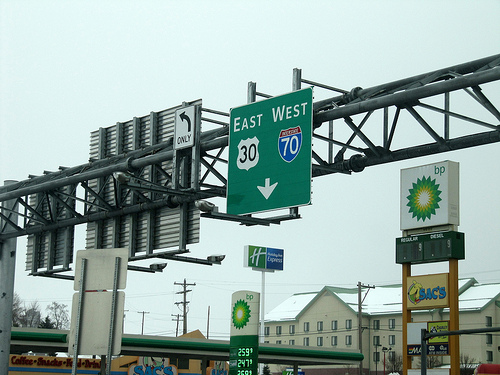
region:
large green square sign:
[225, 88, 314, 217]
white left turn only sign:
[175, 105, 194, 150]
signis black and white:
[172, 105, 195, 151]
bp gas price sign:
[226, 289, 258, 374]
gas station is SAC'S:
[9, 328, 362, 374]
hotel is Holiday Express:
[259, 276, 499, 373]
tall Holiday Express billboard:
[243, 245, 285, 342]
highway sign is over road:
[225, 85, 312, 216]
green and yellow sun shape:
[231, 298, 249, 328]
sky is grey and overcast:
[1, 0, 498, 339]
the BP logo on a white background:
[228, 290, 261, 336]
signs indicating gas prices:
[230, 335, 257, 373]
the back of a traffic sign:
[68, 248, 128, 357]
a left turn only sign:
[172, 103, 197, 148]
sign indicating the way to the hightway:
[224, 85, 312, 218]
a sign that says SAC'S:
[404, 271, 451, 311]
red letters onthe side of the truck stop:
[8, 353, 103, 368]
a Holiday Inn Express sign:
[243, 243, 285, 273]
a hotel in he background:
[260, 278, 498, 373]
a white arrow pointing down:
[255, 173, 279, 203]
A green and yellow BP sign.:
[395, 160, 456, 229]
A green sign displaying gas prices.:
[222, 346, 257, 373]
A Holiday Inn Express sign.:
[246, 247, 286, 268]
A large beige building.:
[262, 278, 497, 370]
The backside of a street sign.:
[67, 248, 124, 355]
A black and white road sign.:
[169, 107, 197, 150]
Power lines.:
[118, 275, 498, 342]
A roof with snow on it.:
[258, 279, 498, 321]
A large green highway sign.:
[229, 87, 315, 214]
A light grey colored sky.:
[2, 2, 499, 340]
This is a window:
[341, 316, 355, 331]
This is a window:
[343, 331, 354, 348]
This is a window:
[328, 315, 338, 331]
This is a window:
[330, 331, 340, 348]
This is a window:
[315, 318, 325, 333]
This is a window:
[313, 335, 325, 350]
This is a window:
[300, 318, 312, 334]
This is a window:
[303, 336, 312, 348]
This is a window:
[288, 322, 298, 337]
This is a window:
[274, 323, 282, 338]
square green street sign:
[220, 83, 317, 214]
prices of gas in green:
[230, 343, 260, 374]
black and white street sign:
[174, 103, 196, 151]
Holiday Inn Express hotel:
[243, 237, 498, 372]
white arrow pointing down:
[256, 173, 281, 203]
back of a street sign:
[55, 241, 129, 371]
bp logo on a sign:
[393, 156, 469, 231]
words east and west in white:
[232, 90, 310, 132]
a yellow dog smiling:
[401, 280, 424, 306]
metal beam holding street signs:
[4, 65, 492, 245]